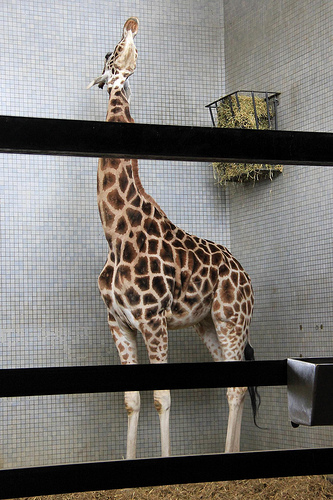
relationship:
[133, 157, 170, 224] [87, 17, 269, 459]
mane of giraffe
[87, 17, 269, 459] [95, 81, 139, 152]
giraffe has neck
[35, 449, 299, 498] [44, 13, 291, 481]
hay beneath giraffe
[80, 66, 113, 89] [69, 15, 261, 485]
ear of giraffe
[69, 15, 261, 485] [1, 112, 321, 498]
giraffe standing in an enclosure